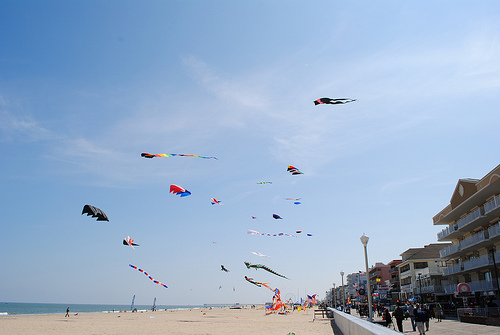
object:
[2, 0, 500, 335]
picture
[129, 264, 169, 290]
kite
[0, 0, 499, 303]
sky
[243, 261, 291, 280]
kite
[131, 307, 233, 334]
yellow number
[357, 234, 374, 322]
pole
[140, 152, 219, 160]
kite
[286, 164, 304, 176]
kite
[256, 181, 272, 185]
kite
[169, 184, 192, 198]
kite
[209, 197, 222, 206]
kite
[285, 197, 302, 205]
kite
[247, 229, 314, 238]
kite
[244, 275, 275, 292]
kite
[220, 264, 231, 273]
kite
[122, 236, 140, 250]
kite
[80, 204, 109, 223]
kite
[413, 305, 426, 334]
people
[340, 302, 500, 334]
sidewalk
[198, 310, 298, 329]
beach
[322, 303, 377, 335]
rail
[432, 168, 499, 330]
building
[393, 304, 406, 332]
person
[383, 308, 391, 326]
person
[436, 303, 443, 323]
person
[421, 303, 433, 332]
person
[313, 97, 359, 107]
kite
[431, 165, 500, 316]
balconies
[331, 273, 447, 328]
boardwalk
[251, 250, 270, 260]
white kite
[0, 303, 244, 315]
ocean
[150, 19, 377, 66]
air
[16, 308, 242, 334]
sand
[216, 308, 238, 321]
sand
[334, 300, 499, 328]
boardwalk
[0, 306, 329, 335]
beach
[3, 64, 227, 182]
clouds